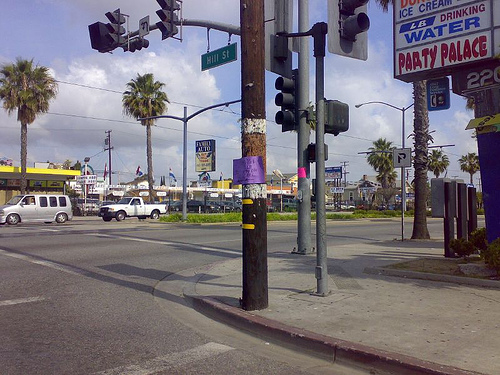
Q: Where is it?
A: This is at the street.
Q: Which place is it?
A: It is a street.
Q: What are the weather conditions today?
A: It is cloudy.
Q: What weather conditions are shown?
A: It is cloudy.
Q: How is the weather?
A: It is cloudy.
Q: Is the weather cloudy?
A: Yes, it is cloudy.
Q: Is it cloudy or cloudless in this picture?
A: It is cloudy.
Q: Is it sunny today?
A: No, it is cloudy.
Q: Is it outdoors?
A: Yes, it is outdoors.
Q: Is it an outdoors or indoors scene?
A: It is outdoors.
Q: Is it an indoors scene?
A: No, it is outdoors.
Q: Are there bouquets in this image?
A: No, there are no bouquets.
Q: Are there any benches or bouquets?
A: No, there are no bouquets or benches.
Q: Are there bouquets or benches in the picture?
A: No, there are no bouquets or benches.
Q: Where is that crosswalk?
A: The crosswalk is on the street.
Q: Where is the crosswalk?
A: The crosswalk is on the street.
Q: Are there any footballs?
A: No, there are no footballs.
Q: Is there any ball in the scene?
A: No, there are no balls.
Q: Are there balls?
A: No, there are no balls.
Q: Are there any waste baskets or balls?
A: No, there are no balls or waste baskets.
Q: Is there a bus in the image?
A: No, there are no buses.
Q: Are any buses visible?
A: No, there are no buses.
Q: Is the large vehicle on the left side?
A: Yes, the van is on the left of the image.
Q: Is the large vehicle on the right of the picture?
A: No, the van is on the left of the image.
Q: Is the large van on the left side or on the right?
A: The van is on the left of the image.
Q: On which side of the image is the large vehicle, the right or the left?
A: The van is on the left of the image.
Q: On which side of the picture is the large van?
A: The van is on the left of the image.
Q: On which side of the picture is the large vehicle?
A: The van is on the left of the image.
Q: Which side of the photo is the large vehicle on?
A: The van is on the left of the image.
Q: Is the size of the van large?
A: Yes, the van is large.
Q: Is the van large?
A: Yes, the van is large.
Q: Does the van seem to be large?
A: Yes, the van is large.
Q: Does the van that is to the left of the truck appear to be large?
A: Yes, the van is large.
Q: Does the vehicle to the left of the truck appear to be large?
A: Yes, the van is large.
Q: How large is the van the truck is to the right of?
A: The van is large.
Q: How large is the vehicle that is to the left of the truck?
A: The van is large.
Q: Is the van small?
A: No, the van is large.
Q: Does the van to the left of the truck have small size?
A: No, the van is large.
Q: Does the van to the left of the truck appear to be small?
A: No, the van is large.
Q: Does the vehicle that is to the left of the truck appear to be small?
A: No, the van is large.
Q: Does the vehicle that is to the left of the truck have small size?
A: No, the van is large.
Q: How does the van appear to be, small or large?
A: The van is large.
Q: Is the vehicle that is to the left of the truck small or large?
A: The van is large.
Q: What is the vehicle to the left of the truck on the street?
A: The vehicle is a van.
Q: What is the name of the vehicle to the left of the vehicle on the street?
A: The vehicle is a van.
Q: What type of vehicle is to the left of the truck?
A: The vehicle is a van.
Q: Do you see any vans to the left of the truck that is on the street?
A: Yes, there is a van to the left of the truck.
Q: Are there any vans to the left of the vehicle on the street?
A: Yes, there is a van to the left of the truck.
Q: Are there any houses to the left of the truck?
A: No, there is a van to the left of the truck.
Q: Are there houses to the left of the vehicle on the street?
A: No, there is a van to the left of the truck.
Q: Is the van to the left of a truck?
A: Yes, the van is to the left of a truck.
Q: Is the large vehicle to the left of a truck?
A: Yes, the van is to the left of a truck.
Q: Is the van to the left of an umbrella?
A: No, the van is to the left of a truck.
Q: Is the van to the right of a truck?
A: No, the van is to the left of a truck.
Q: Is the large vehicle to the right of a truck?
A: No, the van is to the left of a truck.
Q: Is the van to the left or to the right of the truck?
A: The van is to the left of the truck.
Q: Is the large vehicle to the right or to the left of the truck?
A: The van is to the left of the truck.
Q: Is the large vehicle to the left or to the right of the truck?
A: The van is to the left of the truck.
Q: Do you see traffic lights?
A: Yes, there is a traffic light.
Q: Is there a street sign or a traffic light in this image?
A: Yes, there is a traffic light.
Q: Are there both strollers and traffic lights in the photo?
A: No, there is a traffic light but no strollers.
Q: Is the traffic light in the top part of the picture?
A: Yes, the traffic light is in the top of the image.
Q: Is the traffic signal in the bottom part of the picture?
A: No, the traffic signal is in the top of the image.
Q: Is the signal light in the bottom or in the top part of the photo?
A: The signal light is in the top of the image.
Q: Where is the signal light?
A: The signal light is in the street.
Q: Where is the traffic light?
A: The signal light is in the street.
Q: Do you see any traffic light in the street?
A: Yes, there is a traffic light in the street.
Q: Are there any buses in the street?
A: No, there is a traffic light in the street.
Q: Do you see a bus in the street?
A: No, there is a traffic light in the street.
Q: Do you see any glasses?
A: No, there are no glasses.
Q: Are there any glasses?
A: No, there are no glasses.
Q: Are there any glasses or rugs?
A: No, there are no glasses or rugs.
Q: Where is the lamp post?
A: The lamp post is on the street.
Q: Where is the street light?
A: The lamp post is on the street.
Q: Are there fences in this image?
A: No, there are no fences.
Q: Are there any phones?
A: Yes, there is a phone.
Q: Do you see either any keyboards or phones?
A: Yes, there is a phone.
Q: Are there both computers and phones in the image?
A: No, there is a phone but no computers.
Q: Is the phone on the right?
A: Yes, the phone is on the right of the image.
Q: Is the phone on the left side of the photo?
A: No, the phone is on the right of the image.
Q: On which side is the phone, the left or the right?
A: The phone is on the right of the image.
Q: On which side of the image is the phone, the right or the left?
A: The phone is on the right of the image.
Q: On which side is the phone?
A: The phone is on the right of the image.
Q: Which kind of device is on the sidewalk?
A: The device is a phone.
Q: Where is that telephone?
A: The telephone is on the sidewalk.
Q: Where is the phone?
A: The telephone is on the sidewalk.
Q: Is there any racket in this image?
A: No, there are no rackets.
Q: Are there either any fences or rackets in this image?
A: No, there are no rackets or fences.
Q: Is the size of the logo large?
A: Yes, the logo is large.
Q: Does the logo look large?
A: Yes, the logo is large.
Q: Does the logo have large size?
A: Yes, the logo is large.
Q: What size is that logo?
A: The logo is large.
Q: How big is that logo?
A: The logo is large.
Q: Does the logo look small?
A: No, the logo is large.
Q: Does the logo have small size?
A: No, the logo is large.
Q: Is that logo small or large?
A: The logo is large.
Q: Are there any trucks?
A: Yes, there is a truck.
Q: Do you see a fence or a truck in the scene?
A: Yes, there is a truck.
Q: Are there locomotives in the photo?
A: No, there are no locomotives.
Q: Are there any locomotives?
A: No, there are no locomotives.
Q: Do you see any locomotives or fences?
A: No, there are no locomotives or fences.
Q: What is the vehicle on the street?
A: The vehicle is a truck.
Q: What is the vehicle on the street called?
A: The vehicle is a truck.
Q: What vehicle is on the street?
A: The vehicle is a truck.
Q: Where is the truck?
A: The truck is on the street.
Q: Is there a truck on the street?
A: Yes, there is a truck on the street.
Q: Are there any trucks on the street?
A: Yes, there is a truck on the street.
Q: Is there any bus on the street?
A: No, there is a truck on the street.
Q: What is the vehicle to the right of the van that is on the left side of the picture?
A: The vehicle is a truck.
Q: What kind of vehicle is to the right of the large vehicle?
A: The vehicle is a truck.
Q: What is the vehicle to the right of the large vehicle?
A: The vehicle is a truck.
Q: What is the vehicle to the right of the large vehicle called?
A: The vehicle is a truck.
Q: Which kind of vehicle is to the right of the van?
A: The vehicle is a truck.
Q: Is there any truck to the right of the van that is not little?
A: Yes, there is a truck to the right of the van.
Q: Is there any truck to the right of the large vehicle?
A: Yes, there is a truck to the right of the van.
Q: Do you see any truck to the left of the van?
A: No, the truck is to the right of the van.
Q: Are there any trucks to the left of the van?
A: No, the truck is to the right of the van.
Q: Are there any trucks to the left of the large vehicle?
A: No, the truck is to the right of the van.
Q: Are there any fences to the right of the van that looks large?
A: No, there is a truck to the right of the van.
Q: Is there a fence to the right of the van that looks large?
A: No, there is a truck to the right of the van.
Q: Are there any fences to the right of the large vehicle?
A: No, there is a truck to the right of the van.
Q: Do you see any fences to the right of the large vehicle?
A: No, there is a truck to the right of the van.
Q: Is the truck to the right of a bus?
A: No, the truck is to the right of a van.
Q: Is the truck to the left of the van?
A: No, the truck is to the right of the van.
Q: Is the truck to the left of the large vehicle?
A: No, the truck is to the right of the van.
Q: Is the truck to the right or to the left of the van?
A: The truck is to the right of the van.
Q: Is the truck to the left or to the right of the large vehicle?
A: The truck is to the right of the van.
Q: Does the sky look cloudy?
A: Yes, the sky is cloudy.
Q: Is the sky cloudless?
A: No, the sky is cloudy.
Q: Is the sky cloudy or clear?
A: The sky is cloudy.